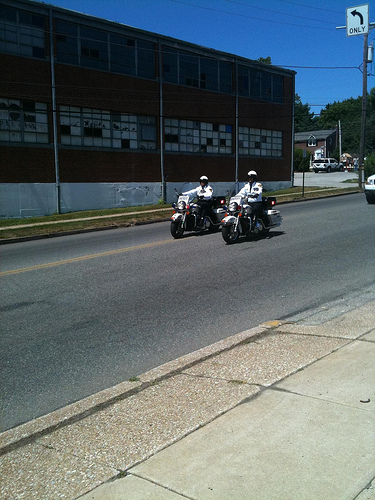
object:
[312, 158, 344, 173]
car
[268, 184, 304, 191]
grass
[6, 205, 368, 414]
road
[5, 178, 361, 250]
curb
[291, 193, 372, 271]
ground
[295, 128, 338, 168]
house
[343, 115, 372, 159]
tree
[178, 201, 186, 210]
headlight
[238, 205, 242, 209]
indicator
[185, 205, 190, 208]
indicator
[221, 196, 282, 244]
bike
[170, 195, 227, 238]
motorcycle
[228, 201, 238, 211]
headlight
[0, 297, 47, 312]
stain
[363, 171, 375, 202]
car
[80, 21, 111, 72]
windows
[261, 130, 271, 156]
windows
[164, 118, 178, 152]
windows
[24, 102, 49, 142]
windows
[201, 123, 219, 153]
windows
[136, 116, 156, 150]
windows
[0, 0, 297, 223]
building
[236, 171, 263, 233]
cop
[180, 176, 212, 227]
cop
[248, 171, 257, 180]
helmet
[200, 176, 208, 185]
helmet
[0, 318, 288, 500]
sidewalk curb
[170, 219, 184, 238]
wheel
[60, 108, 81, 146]
window